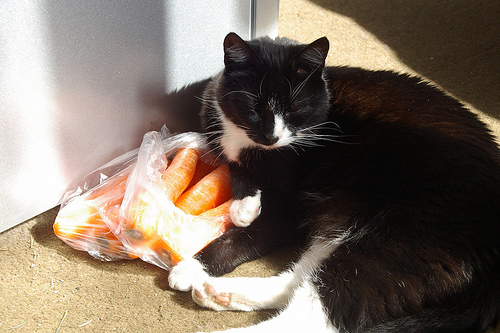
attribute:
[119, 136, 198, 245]
carrot — orange, long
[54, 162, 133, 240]
carrot — orange, long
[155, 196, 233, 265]
carrot — orange, long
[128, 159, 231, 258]
carrot — orange, long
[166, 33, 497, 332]
cat — white, black, alive, asleep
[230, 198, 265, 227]
paws — white, pink, padded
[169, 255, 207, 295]
paw — white, pink, padded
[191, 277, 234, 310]
paw — white, pink, padded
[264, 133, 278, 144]
nose — white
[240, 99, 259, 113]
eye — closed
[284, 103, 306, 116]
eye — closed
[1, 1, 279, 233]
fridge — background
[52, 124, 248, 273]
bag — open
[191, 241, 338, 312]
leg — white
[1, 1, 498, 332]
floor — carpet